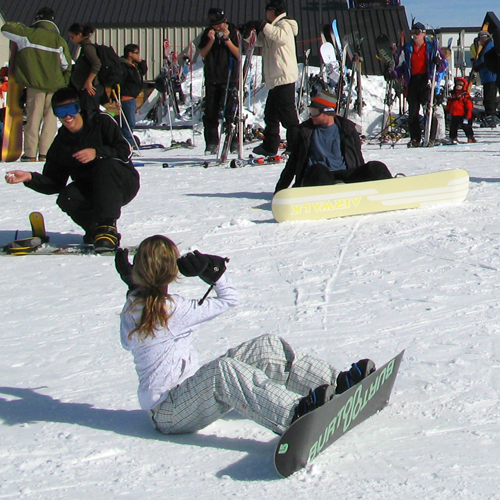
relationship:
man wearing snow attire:
[4, 79, 145, 256] [62, 136, 128, 205]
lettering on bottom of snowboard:
[302, 366, 409, 475] [274, 345, 411, 480]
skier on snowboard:
[104, 233, 408, 475] [258, 340, 425, 480]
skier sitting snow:
[104, 233, 408, 475] [0, 124, 497, 497]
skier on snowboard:
[104, 233, 408, 475] [274, 345, 411, 480]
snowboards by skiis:
[295, 38, 369, 133] [295, 38, 369, 133]